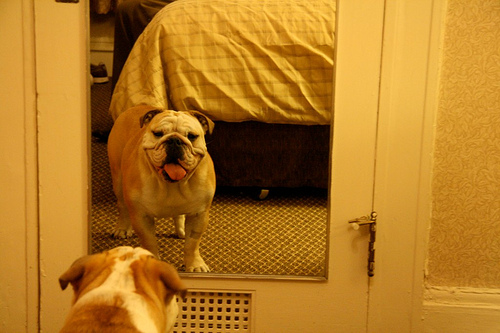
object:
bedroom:
[0, 0, 500, 333]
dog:
[52, 245, 188, 332]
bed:
[113, 0, 335, 199]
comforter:
[108, 0, 337, 125]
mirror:
[87, 0, 336, 281]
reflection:
[107, 105, 217, 273]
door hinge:
[349, 210, 376, 277]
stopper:
[349, 221, 359, 223]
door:
[36, 0, 384, 333]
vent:
[173, 290, 250, 332]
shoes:
[89, 64, 110, 83]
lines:
[185, 54, 304, 59]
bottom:
[204, 121, 331, 199]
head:
[61, 245, 187, 317]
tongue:
[164, 163, 187, 181]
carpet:
[91, 84, 329, 277]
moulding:
[423, 281, 500, 308]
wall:
[420, 0, 498, 333]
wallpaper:
[423, 0, 499, 289]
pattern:
[177, 31, 241, 60]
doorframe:
[0, 0, 39, 332]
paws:
[109, 216, 133, 239]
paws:
[185, 253, 211, 272]